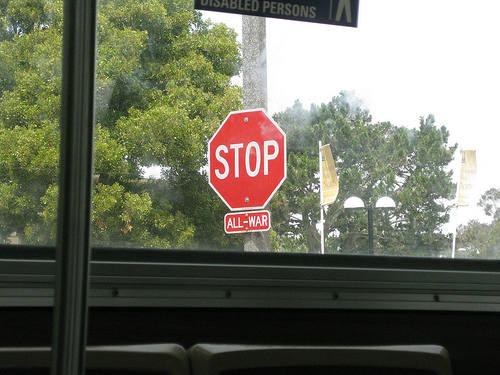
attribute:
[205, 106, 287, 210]
stop sign — red, octagonal, white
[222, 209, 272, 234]
sign — small, red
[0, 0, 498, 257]
trees — green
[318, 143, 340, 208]
flag — yellow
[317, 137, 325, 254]
pole — white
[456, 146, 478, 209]
flag — yellow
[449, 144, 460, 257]
pole — white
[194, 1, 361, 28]
sign — blue, rectangular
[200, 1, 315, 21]
text — white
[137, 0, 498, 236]
sky — overcast, clear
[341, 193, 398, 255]
street lamp — black, white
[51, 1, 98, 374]
rail — grey, inside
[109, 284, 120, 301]
screw — far left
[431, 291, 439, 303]
screw — far right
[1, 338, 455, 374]
chair backs — plastic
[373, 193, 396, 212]
globe — white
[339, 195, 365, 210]
globe — white